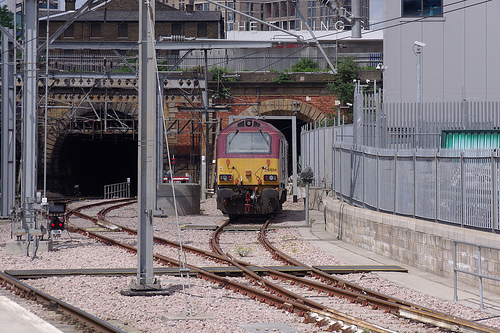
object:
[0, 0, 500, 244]
buildings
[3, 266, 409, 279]
plank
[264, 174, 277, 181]
light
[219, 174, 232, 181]
light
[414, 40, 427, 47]
video camera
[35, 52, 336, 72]
railing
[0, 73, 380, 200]
bridge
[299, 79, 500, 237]
fencing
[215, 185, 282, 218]
metal plate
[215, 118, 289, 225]
train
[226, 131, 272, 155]
windowshield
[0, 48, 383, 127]
bushes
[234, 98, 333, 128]
arch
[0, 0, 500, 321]
wall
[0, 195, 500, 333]
gravel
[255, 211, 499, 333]
tracks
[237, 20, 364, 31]
letters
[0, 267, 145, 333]
track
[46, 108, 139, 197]
archway